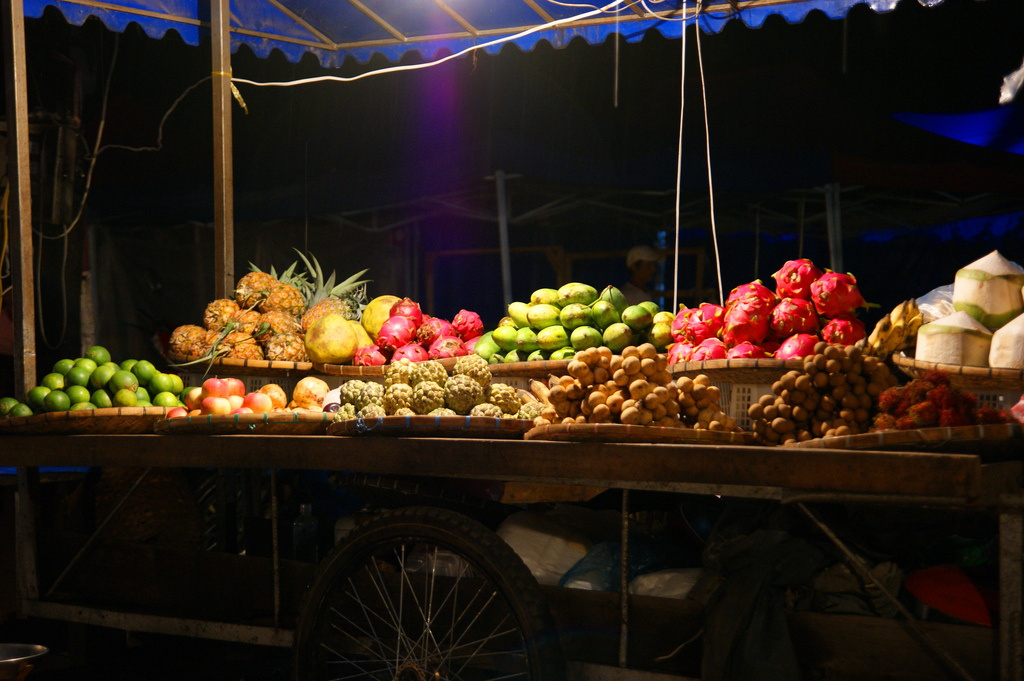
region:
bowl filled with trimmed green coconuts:
[896, 250, 1020, 387]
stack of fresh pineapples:
[162, 259, 349, 368]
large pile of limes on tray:
[7, 338, 179, 425]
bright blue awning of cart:
[4, 2, 944, 75]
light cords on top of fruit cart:
[219, 0, 707, 95]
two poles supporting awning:
[8, 0, 249, 411]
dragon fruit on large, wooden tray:
[669, 252, 866, 383]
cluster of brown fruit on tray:
[526, 338, 758, 446]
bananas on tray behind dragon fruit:
[866, 291, 930, 367]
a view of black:
[438, 143, 634, 239]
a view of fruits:
[209, 228, 1016, 428]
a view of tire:
[318, 455, 575, 668]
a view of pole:
[163, 67, 293, 296]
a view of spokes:
[366, 572, 490, 671]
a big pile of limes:
[26, 335, 154, 452]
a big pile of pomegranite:
[365, 262, 470, 373]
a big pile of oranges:
[541, 347, 716, 443]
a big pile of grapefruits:
[304, 288, 397, 364]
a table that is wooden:
[196, 414, 980, 656]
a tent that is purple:
[263, 22, 570, 98]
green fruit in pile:
[549, 261, 592, 322]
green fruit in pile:
[593, 318, 620, 358]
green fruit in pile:
[632, 293, 659, 319]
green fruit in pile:
[65, 375, 98, 396]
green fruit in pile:
[81, 344, 143, 389]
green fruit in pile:
[144, 357, 192, 428]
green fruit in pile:
[41, 371, 81, 407]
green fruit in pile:
[499, 287, 548, 357]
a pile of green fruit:
[443, 263, 688, 371]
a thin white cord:
[229, 1, 626, 107]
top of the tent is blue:
[18, 1, 1022, 74]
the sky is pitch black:
[2, 4, 1020, 397]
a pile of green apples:
[11, 345, 196, 418]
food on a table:
[13, 244, 1020, 660]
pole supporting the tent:
[207, 3, 250, 313]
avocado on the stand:
[599, 294, 657, 337]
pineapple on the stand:
[442, 341, 509, 398]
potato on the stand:
[610, 335, 669, 393]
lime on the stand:
[89, 351, 153, 405]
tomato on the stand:
[196, 370, 263, 402]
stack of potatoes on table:
[738, 344, 891, 447]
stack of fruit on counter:
[316, 334, 538, 439]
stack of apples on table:
[165, 359, 325, 426]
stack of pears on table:
[4, 325, 186, 433]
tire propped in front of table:
[269, 507, 564, 676]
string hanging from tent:
[655, 1, 745, 312]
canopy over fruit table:
[4, 3, 1022, 83]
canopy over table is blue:
[6, 2, 1022, 82]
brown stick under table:
[788, 496, 988, 674]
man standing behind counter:
[601, 236, 672, 316]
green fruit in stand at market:
[495, 285, 610, 355]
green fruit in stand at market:
[560, 304, 600, 343]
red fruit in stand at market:
[675, 275, 717, 356]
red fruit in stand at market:
[757, 265, 838, 343]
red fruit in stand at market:
[431, 304, 473, 356]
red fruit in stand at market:
[383, 291, 421, 340]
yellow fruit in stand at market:
[313, 312, 365, 370]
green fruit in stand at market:
[29, 338, 81, 408]